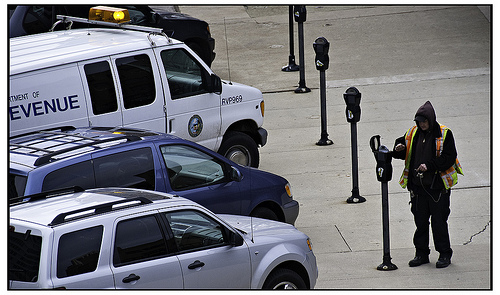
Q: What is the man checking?
A: The metor.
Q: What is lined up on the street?
A: Motors.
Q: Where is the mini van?
A: Second.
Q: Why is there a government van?
A: Collecting revenue.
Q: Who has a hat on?
A: Officer.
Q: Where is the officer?
A: Sidewalk.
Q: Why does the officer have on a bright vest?
A: Visible.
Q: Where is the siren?
A: On the van.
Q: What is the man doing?
A: Feeding a parking meter.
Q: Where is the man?
A: By the parking meter.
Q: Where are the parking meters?
A: On the sidewalk.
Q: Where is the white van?
A: By the blue van.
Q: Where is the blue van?
A: Parked by the grey van.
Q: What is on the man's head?
A: A black hood.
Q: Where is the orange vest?
A: On the man.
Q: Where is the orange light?
A: On top of the white van.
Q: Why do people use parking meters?
A: To pay for parking.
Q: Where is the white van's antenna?
A: Front of the van.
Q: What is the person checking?
A: Meters.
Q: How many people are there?
A: One.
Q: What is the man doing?
A: Taking money from the meters.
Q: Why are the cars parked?
A: Because the owners parked them there.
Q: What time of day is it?
A: Daytime.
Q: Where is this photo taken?
A: On a sidewalk.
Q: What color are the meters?
A: Black.